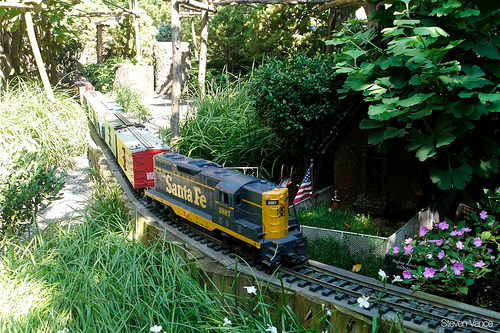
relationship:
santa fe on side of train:
[159, 172, 218, 207] [77, 76, 313, 269]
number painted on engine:
[227, 209, 232, 219] [112, 129, 336, 244]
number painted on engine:
[223, 208, 228, 215] [112, 129, 336, 244]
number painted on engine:
[220, 205, 222, 216] [112, 129, 336, 244]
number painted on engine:
[216, 207, 220, 214] [112, 129, 336, 244]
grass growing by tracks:
[33, 227, 225, 320] [190, 225, 498, 331]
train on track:
[64, 67, 330, 282] [139, 197, 496, 331]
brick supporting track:
[290, 290, 327, 331] [85, 116, 485, 330]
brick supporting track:
[326, 299, 375, 331] [85, 116, 485, 330]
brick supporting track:
[249, 279, 295, 326] [85, 116, 485, 330]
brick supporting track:
[208, 260, 253, 328] [85, 116, 485, 330]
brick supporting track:
[190, 254, 222, 288] [85, 116, 485, 330]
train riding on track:
[77, 76, 313, 269] [85, 116, 485, 330]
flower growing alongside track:
[400, 266, 412, 279] [85, 116, 485, 330]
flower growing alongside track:
[420, 265, 437, 278] [85, 116, 485, 330]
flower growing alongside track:
[390, 244, 400, 254] [85, 116, 485, 330]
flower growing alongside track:
[401, 242, 413, 255] [85, 116, 485, 330]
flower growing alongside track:
[432, 238, 443, 247] [85, 116, 485, 330]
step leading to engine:
[260, 256, 272, 266] [144, 147, 311, 273]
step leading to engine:
[264, 251, 274, 261] [144, 147, 311, 273]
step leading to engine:
[267, 245, 278, 252] [144, 147, 311, 273]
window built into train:
[221, 191, 230, 202] [64, 67, 330, 282]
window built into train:
[214, 190, 223, 202] [64, 67, 330, 282]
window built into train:
[231, 192, 241, 203] [64, 67, 330, 282]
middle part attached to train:
[88, 93, 169, 186] [77, 76, 313, 269]